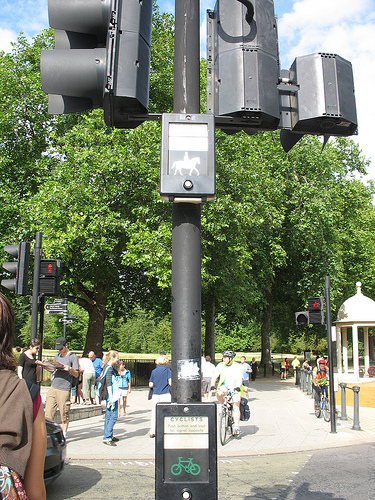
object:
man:
[211, 347, 243, 436]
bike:
[219, 387, 238, 445]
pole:
[171, 204, 203, 409]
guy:
[40, 334, 80, 438]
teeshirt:
[47, 349, 82, 387]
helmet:
[220, 347, 234, 362]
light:
[45, 259, 57, 274]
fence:
[128, 357, 152, 387]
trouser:
[40, 380, 73, 432]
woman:
[98, 348, 119, 451]